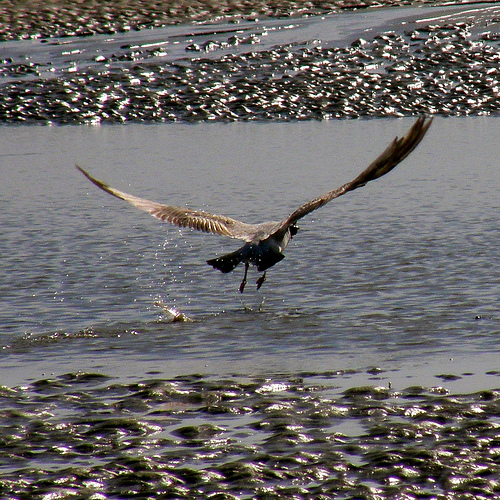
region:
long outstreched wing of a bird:
[76, 151, 245, 253]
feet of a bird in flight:
[232, 268, 275, 300]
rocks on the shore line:
[163, 370, 401, 483]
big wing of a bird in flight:
[282, 112, 451, 262]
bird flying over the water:
[58, 99, 454, 329]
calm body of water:
[350, 243, 422, 332]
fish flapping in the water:
[148, 269, 199, 337]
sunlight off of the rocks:
[82, 25, 399, 135]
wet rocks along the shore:
[105, 58, 304, 126]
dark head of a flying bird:
[286, 218, 303, 240]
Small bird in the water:
[78, 126, 472, 301]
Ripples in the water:
[10, 306, 64, 352]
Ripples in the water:
[76, 310, 127, 353]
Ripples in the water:
[133, 298, 206, 346]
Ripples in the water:
[192, 300, 258, 336]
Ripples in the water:
[292, 310, 356, 361]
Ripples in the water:
[338, 265, 381, 324]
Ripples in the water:
[409, 260, 486, 367]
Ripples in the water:
[390, 182, 455, 251]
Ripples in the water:
[212, 135, 309, 190]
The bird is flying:
[46, 85, 455, 322]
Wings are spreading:
[55, 108, 457, 310]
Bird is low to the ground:
[78, 113, 467, 315]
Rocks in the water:
[0, 340, 497, 494]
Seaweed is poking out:
[11, 355, 486, 498]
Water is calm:
[14, 223, 167, 348]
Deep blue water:
[141, 138, 287, 178]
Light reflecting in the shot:
[70, 18, 264, 77]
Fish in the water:
[128, 280, 208, 348]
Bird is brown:
[54, 107, 465, 312]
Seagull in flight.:
[63, 109, 464, 285]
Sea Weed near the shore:
[1, 379, 499, 496]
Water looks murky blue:
[352, 203, 498, 358]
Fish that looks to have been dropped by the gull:
[142, 289, 204, 337]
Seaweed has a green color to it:
[215, 457, 283, 484]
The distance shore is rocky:
[2, 7, 321, 23]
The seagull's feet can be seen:
[234, 261, 271, 299]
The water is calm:
[33, 128, 359, 173]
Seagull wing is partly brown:
[151, 206, 235, 239]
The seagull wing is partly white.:
[105, 186, 165, 215]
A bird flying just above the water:
[39, 108, 444, 297]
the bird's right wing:
[275, 110, 436, 247]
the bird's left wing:
[65, 157, 272, 244]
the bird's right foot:
[254, 266, 271, 296]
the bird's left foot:
[233, 260, 250, 295]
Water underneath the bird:
[0, 113, 497, 364]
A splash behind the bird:
[21, 223, 206, 333]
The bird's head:
[285, 218, 300, 239]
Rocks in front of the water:
[1, 5, 494, 113]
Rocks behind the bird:
[3, 360, 497, 496]